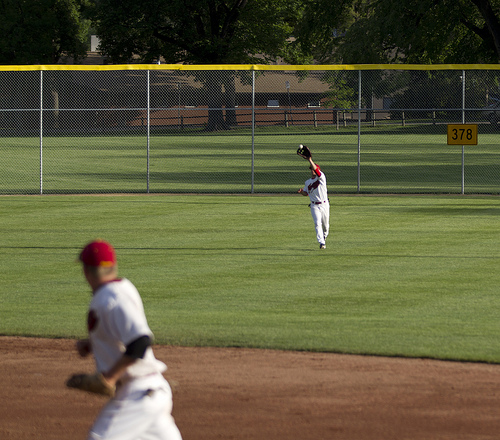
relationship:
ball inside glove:
[298, 141, 303, 151] [295, 145, 311, 160]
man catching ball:
[293, 154, 332, 250] [298, 141, 303, 151]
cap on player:
[76, 241, 117, 265] [65, 241, 181, 439]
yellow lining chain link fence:
[1, 61, 498, 70] [1, 66, 500, 199]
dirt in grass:
[1, 334, 498, 439] [1, 119, 496, 363]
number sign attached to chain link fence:
[446, 123, 478, 146] [1, 66, 500, 199]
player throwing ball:
[65, 241, 181, 439] [298, 141, 303, 151]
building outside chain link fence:
[11, 53, 348, 131] [1, 66, 500, 199]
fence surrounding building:
[3, 100, 499, 133] [11, 53, 348, 131]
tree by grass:
[1, 4, 101, 137] [1, 119, 496, 363]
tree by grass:
[94, 3, 304, 134] [1, 119, 496, 363]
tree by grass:
[273, 2, 397, 128] [1, 119, 496, 363]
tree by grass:
[339, 0, 497, 129] [1, 119, 496, 363]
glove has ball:
[295, 145, 311, 160] [298, 141, 303, 151]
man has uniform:
[293, 154, 332, 250] [305, 167, 332, 250]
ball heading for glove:
[298, 141, 303, 151] [295, 145, 311, 160]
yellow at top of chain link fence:
[1, 61, 498, 70] [1, 66, 500, 199]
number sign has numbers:
[446, 123, 478, 146] [450, 126, 475, 143]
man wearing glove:
[293, 154, 332, 250] [295, 145, 311, 160]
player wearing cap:
[65, 241, 181, 439] [76, 241, 117, 265]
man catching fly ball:
[293, 154, 332, 250] [298, 141, 303, 151]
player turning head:
[65, 241, 181, 439] [78, 239, 119, 285]